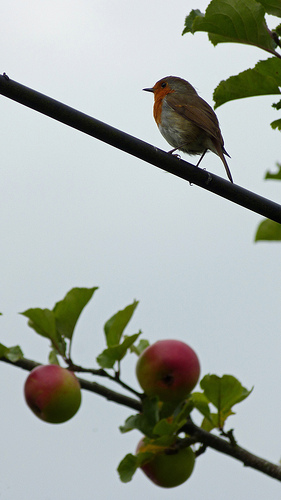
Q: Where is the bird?
A: On an apple tree branch.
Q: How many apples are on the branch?
A: 3.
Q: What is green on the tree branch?
A: Leaves.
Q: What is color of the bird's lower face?
A: Orange.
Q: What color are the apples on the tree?
A: Red and green.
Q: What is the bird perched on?
A: Straight rod.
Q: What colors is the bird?
A: Gray and orange.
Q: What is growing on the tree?
A: Apples.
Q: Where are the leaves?
A: On the branch.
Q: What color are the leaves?
A: Green.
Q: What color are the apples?
A: Green and Red.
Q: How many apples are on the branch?
A: 3.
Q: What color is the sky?
A: Light blue.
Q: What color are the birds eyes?
A: Black.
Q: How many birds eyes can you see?
A: 1.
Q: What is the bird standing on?
A: A wire.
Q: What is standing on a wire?
A: A bird.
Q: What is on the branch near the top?
A: Bird.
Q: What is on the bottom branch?
A: Apples.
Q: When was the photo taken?
A: Daytime.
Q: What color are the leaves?
A: Green.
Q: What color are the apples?
A: Red and green.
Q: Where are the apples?
A: Bottom branch.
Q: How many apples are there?
A: Three.